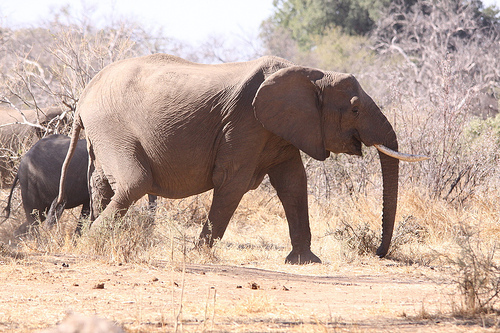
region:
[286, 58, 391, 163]
the head of an elephant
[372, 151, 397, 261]
the trunk of an elephant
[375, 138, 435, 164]
the white tusk of an elephant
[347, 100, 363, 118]
the eye of an elephant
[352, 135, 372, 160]
the mouth of an elephant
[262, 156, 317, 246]
the leg of an elephant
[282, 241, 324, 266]
the foot of an elephant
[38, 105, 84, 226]
the tail of an elephant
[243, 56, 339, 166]
the ear of an elephant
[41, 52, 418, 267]
a gray elephant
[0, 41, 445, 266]
Two elephants near each other.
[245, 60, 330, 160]
The elephant has an ear.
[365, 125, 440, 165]
The elephant has a tusk.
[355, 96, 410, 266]
The elephant has a trunk.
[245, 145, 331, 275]
A front leg on the elephant.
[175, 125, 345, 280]
The elephant has two front legs.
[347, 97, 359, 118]
The elephant has an eye.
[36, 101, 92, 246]
The elephant has a tail.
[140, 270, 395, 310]
Dirt is on the ground.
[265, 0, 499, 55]
Trees in the distance.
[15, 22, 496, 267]
elephants in the wild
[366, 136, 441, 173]
white tusks of elephant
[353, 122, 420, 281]
long trunk of elephant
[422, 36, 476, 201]
trees with no leaves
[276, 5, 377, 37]
trees in the distance with green leaves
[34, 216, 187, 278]
tall brown grass near elephants foot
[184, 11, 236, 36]
bright clear sky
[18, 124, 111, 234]
smaller elephant behind bigger one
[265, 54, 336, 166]
large ears of elephant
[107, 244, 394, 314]
brown dirt for elephants to walk on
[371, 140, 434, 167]
white elephant tusk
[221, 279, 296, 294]
brown rocks on ground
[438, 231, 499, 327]
a dead brown shrub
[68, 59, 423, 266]
large brown elephant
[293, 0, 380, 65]
trees with green leaves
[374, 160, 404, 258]
large brown elephant trunk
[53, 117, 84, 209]
brown elephant tail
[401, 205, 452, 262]
brown grass growing on ground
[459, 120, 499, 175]
a tall bush with green leaves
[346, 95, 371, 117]
eye of large elephant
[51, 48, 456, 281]
a large grey elephant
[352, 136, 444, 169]
a large white elephant tusk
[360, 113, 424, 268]
a large grey elephant trunk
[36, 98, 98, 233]
large tail of an elephant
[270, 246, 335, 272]
large elephant foot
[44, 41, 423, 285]
elephant with giant ear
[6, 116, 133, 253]
smaller grey elephant behind the other elelphant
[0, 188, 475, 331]
the ground is dry and dirty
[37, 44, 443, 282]
large elephant walking in the dirt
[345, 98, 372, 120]
eye of an elephant